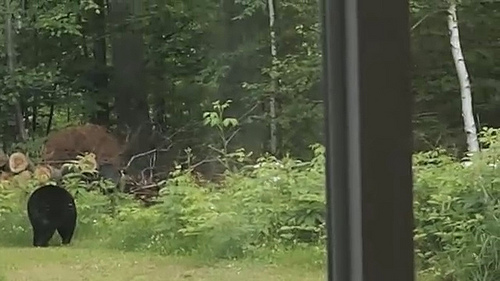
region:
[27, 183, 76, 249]
black bear walking in yard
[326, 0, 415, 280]
frame in middle of a window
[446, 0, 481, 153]
tree with white bark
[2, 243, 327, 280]
grassy yard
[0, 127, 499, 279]
weeds growing on edge of yard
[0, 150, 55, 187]
logs stacked behind weeds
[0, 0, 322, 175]
trees standing on edge of yard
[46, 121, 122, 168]
brown object on edge of yard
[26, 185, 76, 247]
bear walking away from window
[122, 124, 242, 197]
dead limbs sitting on ground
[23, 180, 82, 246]
BLACK BEAR WAKING IN WOODS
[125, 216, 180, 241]
GREEN UNDERGROWTH IN WOODS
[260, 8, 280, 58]
PART OF POPLAR TREE TRUNK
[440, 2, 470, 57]
PART OF POPLAR TREE TRUNK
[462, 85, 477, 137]
PART OF POPLAR TREE TRUNK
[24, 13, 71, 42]
GREEN TREES IN DISTANCE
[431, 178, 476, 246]
GREEN UNDERGROWTH OF WOODS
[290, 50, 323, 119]
GREEN SUMMER TREE LEAVES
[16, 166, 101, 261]
black bear in grass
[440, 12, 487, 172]
tree trunk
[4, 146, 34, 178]
tree log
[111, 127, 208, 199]
tree branches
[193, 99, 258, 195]
tall green plant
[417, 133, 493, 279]
foliage under tree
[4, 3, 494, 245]
trees and foliage behind grass field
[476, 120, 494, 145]
leaves on green stems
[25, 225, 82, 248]
back bear legs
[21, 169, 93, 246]
black bear is standing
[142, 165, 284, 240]
bushes next to the bear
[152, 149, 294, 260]
bushes have green leaves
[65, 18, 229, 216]
brown wood on trees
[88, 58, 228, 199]
trunks on the trees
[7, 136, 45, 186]
pieces of wood behind the bear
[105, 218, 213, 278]
the grass is green and brown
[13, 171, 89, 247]
bear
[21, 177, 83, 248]
black bear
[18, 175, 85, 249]
black bear in green forest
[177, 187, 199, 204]
green leaves on brown plants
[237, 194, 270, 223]
green leaves on brown plants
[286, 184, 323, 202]
green leaves on brown plants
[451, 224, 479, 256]
green leaves on brown plants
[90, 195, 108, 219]
green leaves on brown plants